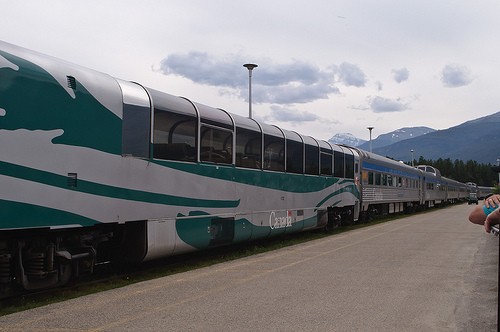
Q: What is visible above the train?
A: Sky.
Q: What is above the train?
A: Sky.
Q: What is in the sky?
A: Clouds.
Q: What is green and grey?
A: Train.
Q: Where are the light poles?
A: Behind the train.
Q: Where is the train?
A: On the tracks.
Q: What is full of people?
A: Train.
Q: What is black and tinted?
A: Windows.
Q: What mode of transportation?
A: Train.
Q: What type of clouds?
A: Puffy.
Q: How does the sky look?
A: Cloudy.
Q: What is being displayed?
A: Green train.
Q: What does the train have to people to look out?
A: Windows.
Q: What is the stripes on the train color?
A: Blue.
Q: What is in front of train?
A: Platform.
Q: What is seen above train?
A: Clouds.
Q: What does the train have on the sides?
A: Design.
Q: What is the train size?
A: Large passenger train.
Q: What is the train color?
A: Green and silver.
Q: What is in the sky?
A: Clouds.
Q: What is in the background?
A: Mountains.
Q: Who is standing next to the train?
A: People.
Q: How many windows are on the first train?
A: 9.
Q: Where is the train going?
A: Canada.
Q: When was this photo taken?
A: Daylight.